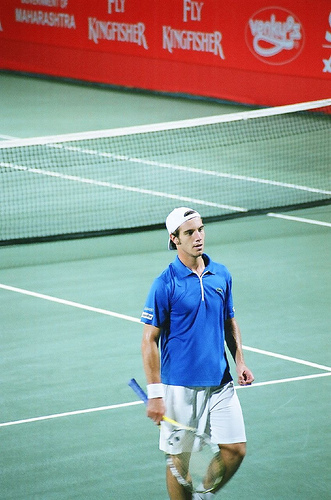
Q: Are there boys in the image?
A: No, there are no boys.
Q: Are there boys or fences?
A: No, there are no boys or fences.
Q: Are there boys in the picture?
A: No, there are no boys.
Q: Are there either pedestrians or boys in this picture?
A: No, there are no boys or pedestrians.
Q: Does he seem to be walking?
A: Yes, the man is walking.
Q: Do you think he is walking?
A: Yes, the man is walking.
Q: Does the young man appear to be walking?
A: Yes, the man is walking.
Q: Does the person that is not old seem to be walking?
A: Yes, the man is walking.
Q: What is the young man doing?
A: The man is walking.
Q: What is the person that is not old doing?
A: The man is walking.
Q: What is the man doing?
A: The man is walking.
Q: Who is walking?
A: The man is walking.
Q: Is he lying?
A: No, the man is walking.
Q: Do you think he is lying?
A: No, the man is walking.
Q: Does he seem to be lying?
A: No, the man is walking.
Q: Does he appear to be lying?
A: No, the man is walking.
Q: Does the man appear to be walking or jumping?
A: The man is walking.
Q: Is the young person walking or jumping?
A: The man is walking.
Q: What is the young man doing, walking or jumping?
A: The man is walking.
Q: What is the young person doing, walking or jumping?
A: The man is walking.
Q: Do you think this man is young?
A: Yes, the man is young.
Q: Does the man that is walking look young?
A: Yes, the man is young.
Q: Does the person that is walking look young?
A: Yes, the man is young.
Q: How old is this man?
A: The man is young.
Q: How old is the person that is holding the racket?
A: The man is young.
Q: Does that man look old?
A: No, the man is young.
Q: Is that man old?
A: No, the man is young.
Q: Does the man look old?
A: No, the man is young.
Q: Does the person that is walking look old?
A: No, the man is young.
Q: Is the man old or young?
A: The man is young.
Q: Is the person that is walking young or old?
A: The man is young.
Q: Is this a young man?
A: Yes, this is a young man.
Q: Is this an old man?
A: No, this is a young man.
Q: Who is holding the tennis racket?
A: The man is holding the tennis racket.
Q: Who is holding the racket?
A: The man is holding the tennis racket.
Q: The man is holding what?
A: The man is holding the racket.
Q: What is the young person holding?
A: The man is holding the racket.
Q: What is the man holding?
A: The man is holding the racket.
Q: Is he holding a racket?
A: Yes, the man is holding a racket.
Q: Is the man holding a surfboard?
A: No, the man is holding a racket.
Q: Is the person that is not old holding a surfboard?
A: No, the man is holding a racket.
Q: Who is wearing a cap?
A: The man is wearing a cap.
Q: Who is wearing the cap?
A: The man is wearing a cap.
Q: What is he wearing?
A: The man is wearing a cap.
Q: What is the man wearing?
A: The man is wearing a cap.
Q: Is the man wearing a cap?
A: Yes, the man is wearing a cap.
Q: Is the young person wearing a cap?
A: Yes, the man is wearing a cap.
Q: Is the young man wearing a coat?
A: No, the man is wearing a cap.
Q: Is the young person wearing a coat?
A: No, the man is wearing a cap.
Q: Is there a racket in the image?
A: Yes, there is a racket.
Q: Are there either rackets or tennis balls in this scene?
A: Yes, there is a racket.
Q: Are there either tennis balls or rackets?
A: Yes, there is a racket.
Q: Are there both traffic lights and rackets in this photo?
A: No, there is a racket but no traffic lights.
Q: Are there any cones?
A: No, there are no cones.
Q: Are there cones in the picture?
A: No, there are no cones.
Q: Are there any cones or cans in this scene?
A: No, there are no cones or cans.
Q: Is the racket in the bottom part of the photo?
A: Yes, the racket is in the bottom of the image.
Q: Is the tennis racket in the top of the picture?
A: No, the tennis racket is in the bottom of the image.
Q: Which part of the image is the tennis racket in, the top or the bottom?
A: The tennis racket is in the bottom of the image.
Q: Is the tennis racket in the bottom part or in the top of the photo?
A: The tennis racket is in the bottom of the image.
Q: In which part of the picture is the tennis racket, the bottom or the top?
A: The tennis racket is in the bottom of the image.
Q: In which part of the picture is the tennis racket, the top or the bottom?
A: The tennis racket is in the bottom of the image.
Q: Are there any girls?
A: No, there are no girls.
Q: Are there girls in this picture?
A: No, there are no girls.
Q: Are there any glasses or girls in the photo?
A: No, there are no girls or glasses.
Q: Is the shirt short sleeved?
A: Yes, the shirt is short sleeved.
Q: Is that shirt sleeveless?
A: No, the shirt is short sleeved.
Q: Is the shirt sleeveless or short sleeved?
A: The shirt is short sleeved.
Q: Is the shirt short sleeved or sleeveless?
A: The shirt is short sleeved.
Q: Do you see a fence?
A: No, there are no fences.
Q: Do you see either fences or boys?
A: No, there are no fences or boys.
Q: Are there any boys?
A: No, there are no boys.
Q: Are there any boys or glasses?
A: No, there are no boys or glasses.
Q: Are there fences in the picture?
A: No, there are no fences.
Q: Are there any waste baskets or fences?
A: No, there are no fences or waste baskets.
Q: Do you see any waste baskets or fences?
A: No, there are no fences or waste baskets.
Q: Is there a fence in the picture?
A: No, there are no fences.